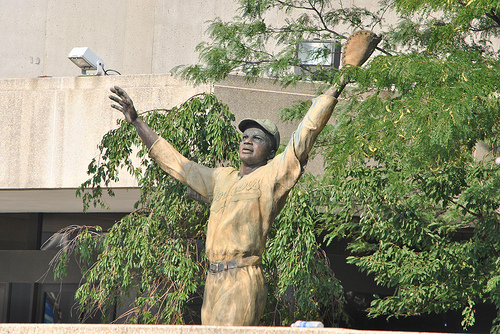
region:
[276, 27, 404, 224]
Hand of a portrait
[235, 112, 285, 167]
Head of a portrait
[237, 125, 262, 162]
Face of a portrait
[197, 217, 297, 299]
Waist of a portrait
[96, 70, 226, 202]
Hand of a portrait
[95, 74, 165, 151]
Hand of a portrait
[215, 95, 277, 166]
Head of a portrait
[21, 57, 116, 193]
Wall of a building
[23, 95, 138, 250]
Wall of a building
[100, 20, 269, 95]
Wall of a building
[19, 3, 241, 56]
Wall of a building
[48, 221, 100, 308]
green needles on the tree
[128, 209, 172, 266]
green needles on the tree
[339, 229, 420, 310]
green needles on the tree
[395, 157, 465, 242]
green needles on the tree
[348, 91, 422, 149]
green needles on the tree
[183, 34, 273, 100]
green needles on the tree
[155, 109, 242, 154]
green needles on the tree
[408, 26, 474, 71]
green needles on the tree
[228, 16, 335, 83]
green needles on the tree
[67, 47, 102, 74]
square light facing downward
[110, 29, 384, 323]
statue of baseball player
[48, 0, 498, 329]
green leaves on trees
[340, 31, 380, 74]
mitt on player's hand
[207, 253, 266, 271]
belt on statue pants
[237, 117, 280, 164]
cap on statue head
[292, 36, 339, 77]
glass on box shaped light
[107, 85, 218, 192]
extended arm in sleeve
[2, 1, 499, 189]
cement surface of building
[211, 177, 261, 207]
name of team on shirt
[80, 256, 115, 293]
Small green leaves on a branch of a tree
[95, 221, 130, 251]
Small green leaves on a branch of a tree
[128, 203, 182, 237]
Small green leaves on a branch of a tree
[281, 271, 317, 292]
Small green leaves on a branch of a tree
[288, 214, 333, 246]
Small green leaves on a branch of a tree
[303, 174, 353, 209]
Small green leaves on a branch of a tree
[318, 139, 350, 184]
Small green leaves on a branch of a tree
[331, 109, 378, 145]
Small green leaves on a branch of a tree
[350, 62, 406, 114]
Small green leaves on a branch of a tree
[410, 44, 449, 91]
Small green leaves on a branch of a tree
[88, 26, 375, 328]
a statue of a man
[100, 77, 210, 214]
a hand of a statue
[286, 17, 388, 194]
a hand of a statue